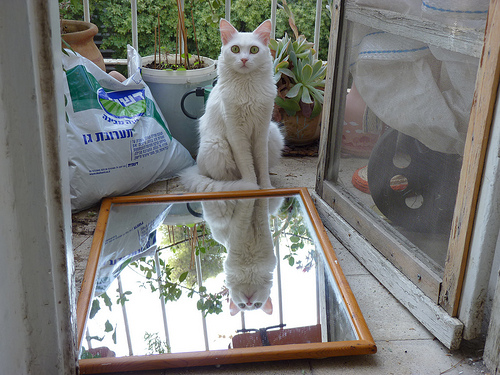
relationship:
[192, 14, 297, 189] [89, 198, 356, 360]
cat in mirror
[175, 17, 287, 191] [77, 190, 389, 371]
cat in mirror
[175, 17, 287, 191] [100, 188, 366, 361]
cat in mirror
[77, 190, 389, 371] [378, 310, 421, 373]
mirror in ground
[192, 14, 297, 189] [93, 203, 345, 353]
cat in mirror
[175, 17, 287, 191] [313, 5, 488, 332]
cat in front of a door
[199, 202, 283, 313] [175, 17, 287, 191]
reflection of cat